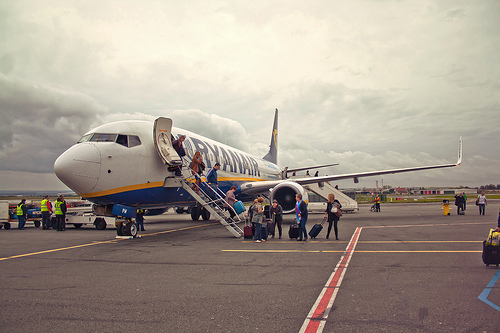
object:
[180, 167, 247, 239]
stairs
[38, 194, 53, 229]
man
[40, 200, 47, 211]
vest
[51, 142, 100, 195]
nose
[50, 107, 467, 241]
plane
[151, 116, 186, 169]
door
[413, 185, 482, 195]
building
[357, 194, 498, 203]
grass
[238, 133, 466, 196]
wing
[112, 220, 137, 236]
wheel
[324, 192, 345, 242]
person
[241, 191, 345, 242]
group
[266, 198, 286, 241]
person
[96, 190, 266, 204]
belly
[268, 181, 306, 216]
engine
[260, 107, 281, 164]
tail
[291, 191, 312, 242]
person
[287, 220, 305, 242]
bag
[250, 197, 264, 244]
person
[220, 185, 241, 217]
person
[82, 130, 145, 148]
windshield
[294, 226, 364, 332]
line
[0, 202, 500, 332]
tarmac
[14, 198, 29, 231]
worker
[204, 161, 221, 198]
person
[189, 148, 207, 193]
woman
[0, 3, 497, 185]
clouds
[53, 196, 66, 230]
worker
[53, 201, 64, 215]
vest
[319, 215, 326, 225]
handle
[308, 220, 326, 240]
luggage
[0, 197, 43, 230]
cart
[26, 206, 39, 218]
luggage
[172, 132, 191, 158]
person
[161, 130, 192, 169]
doorway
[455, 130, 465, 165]
tip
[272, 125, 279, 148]
logo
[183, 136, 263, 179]
ryanair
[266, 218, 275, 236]
luggage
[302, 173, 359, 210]
ramp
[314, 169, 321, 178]
passenger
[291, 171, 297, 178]
passenger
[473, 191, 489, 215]
man